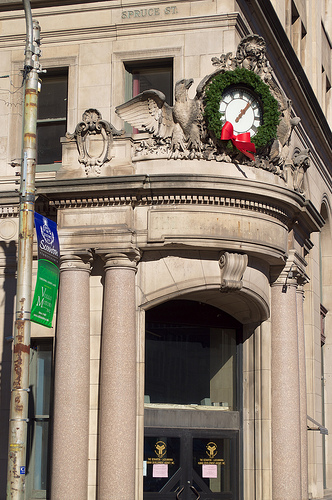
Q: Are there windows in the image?
A: Yes, there is a window.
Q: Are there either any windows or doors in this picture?
A: Yes, there is a window.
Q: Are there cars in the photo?
A: No, there are no cars.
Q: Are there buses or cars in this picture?
A: No, there are no cars or buses.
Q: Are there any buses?
A: No, there are no buses.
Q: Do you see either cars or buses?
A: No, there are no buses or cars.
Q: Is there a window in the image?
A: Yes, there is a window.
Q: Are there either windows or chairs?
A: Yes, there is a window.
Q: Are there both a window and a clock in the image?
A: Yes, there are both a window and a clock.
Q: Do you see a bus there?
A: No, there are no buses.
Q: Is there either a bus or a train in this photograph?
A: No, there are no buses or trains.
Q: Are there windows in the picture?
A: Yes, there is a window.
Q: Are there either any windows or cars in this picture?
A: Yes, there is a window.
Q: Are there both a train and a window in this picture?
A: No, there is a window but no trains.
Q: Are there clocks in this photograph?
A: Yes, there is a clock.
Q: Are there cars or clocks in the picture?
A: Yes, there is a clock.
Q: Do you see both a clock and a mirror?
A: No, there is a clock but no mirrors.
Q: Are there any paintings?
A: No, there are no paintings.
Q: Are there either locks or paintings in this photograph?
A: No, there are no paintings or locks.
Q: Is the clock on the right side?
A: Yes, the clock is on the right of the image.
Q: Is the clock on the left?
A: No, the clock is on the right of the image.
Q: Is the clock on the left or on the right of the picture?
A: The clock is on the right of the image.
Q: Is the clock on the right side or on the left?
A: The clock is on the right of the image.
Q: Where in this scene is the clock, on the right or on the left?
A: The clock is on the right of the image.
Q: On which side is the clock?
A: The clock is on the right of the image.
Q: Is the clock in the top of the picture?
A: Yes, the clock is in the top of the image.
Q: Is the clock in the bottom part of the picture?
A: No, the clock is in the top of the image.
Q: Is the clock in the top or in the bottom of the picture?
A: The clock is in the top of the image.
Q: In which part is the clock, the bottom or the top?
A: The clock is in the top of the image.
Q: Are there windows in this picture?
A: Yes, there is a window.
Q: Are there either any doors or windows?
A: Yes, there is a window.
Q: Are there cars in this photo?
A: No, there are no cars.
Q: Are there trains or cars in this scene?
A: No, there are no cars or trains.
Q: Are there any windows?
A: Yes, there is a window.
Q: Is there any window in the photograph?
A: Yes, there is a window.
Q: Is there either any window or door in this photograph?
A: Yes, there is a window.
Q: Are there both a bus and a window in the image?
A: No, there is a window but no buses.